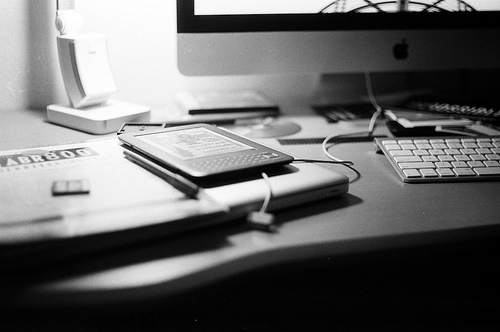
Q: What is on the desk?
A: A PDA.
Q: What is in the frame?
A: An Apple computer.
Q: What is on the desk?
A: Several electronics.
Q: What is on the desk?
A: Electric cords.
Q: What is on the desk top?
A: Electrical gadgets.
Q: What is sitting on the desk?
A: A magazine.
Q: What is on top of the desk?
A: A kindle.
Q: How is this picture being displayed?
A: Black and white.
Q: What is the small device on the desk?
A: Ereader.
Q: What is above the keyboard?
A: Monitor.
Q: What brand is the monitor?
A: Apple.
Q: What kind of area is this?
A: Workspace.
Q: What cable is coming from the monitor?
A: Usb cable.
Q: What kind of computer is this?
A: Desktop.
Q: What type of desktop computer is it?
A: A mac.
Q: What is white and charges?
A: A cable.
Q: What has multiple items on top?
A: A desk.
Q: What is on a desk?
A: Electronic.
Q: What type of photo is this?
A: Black and white.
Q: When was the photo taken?
A: During the day.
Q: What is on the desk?
A: A computer.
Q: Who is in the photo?
A: No one.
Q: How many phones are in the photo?
A: One.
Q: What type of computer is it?
A: Apple.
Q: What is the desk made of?
A: Wood.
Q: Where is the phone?
A: The front of the desk.